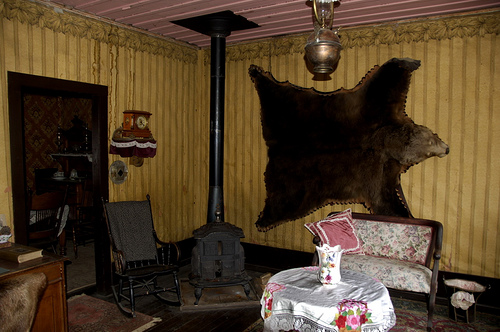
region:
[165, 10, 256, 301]
Black chimney sitting on the ground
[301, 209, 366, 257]
Pink pillow on sofa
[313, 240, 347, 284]
Floral vase on table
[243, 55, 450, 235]
Brown bear on wall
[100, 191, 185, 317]
Rocking chair next to chimney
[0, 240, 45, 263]
Book on top of counter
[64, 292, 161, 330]
Rug in front of doorway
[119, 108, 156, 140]
Small wooden clock above black rocking chair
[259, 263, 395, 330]
Tablecloth is white with floral design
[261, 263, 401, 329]
Table in front of sofa chair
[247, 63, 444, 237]
Brown bear pelt on wall.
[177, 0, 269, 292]
Old style black furnace.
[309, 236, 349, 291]
White vase on table.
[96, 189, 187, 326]
Black wooden rocking chair.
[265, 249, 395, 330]
Round table with white table cloth.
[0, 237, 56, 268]
A hard covered book.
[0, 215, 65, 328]
A wooden counter space.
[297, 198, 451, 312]
Single pillow on seat.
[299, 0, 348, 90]
Bronze metal light fixture.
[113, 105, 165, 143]
Antique wall clock.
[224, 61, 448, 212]
a bearskin rug hanging on the wall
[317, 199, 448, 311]
an old antique wooden sofa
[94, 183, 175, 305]
an old antique wooden rocking chair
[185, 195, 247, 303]
an old fashioned iron stove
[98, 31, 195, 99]
a striped patterned wall paper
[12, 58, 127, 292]
a small wooden door frame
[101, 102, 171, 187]
a small brown lamp hanging on the wall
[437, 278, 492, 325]
an old antique piece of furniture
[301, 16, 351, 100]
a small lamp hanging on the ceiling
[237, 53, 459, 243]
bear hanging on the wal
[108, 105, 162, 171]
clock hanging on the wall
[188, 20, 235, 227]
black pipe running down from the ceiling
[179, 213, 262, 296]
black fireplace in a corner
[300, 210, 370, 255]
red and white pillow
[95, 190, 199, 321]
rocking chair near the door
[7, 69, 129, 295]
dark door frame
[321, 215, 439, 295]
flower patterned fabric on the couch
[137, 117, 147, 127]
two black clock hands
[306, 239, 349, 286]
A white vase on a table.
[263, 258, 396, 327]
A round table with a white table cloth.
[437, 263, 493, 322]
An antique garbage can.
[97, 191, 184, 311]
A black wooden rocking chair.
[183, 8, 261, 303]
An old style black furnace.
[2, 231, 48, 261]
A hard covered brown book.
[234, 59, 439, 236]
A brown bear pelt on the wall.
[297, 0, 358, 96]
A bronze light fixture on the ceiling.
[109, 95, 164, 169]
A wooden clock on the wall.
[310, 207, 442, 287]
A single pillow on the chair.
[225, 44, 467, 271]
a bear hide on the wall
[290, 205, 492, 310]
this seat has a floral pattern on the seat and back rest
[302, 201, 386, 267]
this is a pink pillow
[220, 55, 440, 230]
bear skin on the wall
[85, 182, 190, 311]
a black rocking chair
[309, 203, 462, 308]
a small floral sofa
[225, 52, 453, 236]
the bear skin is brown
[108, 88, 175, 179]
lamp next to the wall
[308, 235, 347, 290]
a white floral vase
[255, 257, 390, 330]
a white table cloth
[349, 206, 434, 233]
brown trim on sofa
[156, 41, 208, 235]
wallpaper on the wall